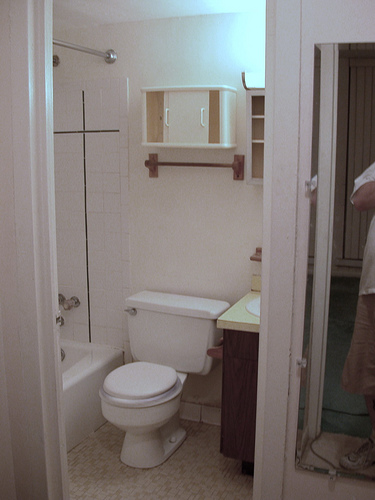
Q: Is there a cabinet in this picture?
A: Yes, there is a cabinet.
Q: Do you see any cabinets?
A: Yes, there is a cabinet.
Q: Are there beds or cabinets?
A: Yes, there is a cabinet.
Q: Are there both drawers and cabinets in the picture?
A: No, there is a cabinet but no drawers.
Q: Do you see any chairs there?
A: No, there are no chairs.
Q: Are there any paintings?
A: No, there are no paintings.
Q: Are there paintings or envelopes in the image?
A: No, there are no paintings or envelopes.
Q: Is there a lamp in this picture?
A: No, there are no lamps.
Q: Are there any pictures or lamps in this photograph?
A: No, there are no lamps or pictures.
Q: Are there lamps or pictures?
A: No, there are no lamps or pictures.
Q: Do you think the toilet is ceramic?
A: Yes, the toilet is ceramic.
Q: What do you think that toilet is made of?
A: The toilet is made of porcelain.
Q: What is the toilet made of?
A: The toilet is made of porcelain.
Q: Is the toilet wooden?
A: No, the toilet is ceramic.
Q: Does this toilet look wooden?
A: No, the toilet is ceramic.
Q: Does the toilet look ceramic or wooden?
A: The toilet is ceramic.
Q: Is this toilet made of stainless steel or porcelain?
A: The toilet is made of porcelain.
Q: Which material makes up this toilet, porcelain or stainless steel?
A: The toilet is made of porcelain.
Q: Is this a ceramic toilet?
A: Yes, this is a ceramic toilet.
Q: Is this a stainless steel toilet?
A: No, this is a ceramic toilet.